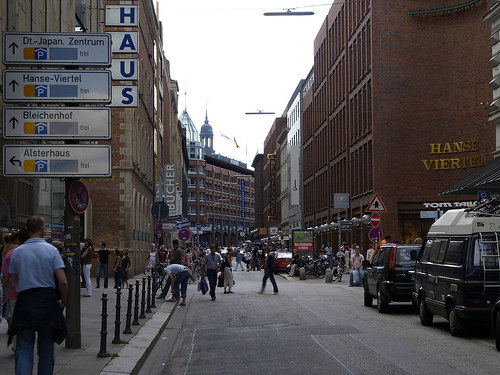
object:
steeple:
[204, 104, 209, 124]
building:
[0, 0, 500, 288]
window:
[444, 240, 464, 263]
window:
[428, 239, 447, 263]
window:
[473, 239, 498, 267]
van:
[412, 208, 500, 331]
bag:
[349, 270, 363, 287]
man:
[347, 245, 364, 287]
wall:
[371, 0, 495, 246]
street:
[0, 235, 500, 375]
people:
[223, 248, 235, 295]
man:
[7, 214, 70, 375]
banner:
[166, 165, 177, 211]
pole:
[96, 292, 109, 357]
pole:
[110, 285, 121, 343]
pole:
[122, 283, 134, 335]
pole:
[145, 275, 152, 314]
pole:
[150, 272, 156, 308]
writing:
[422, 139, 486, 170]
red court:
[88, 273, 152, 355]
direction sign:
[3, 32, 112, 67]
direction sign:
[2, 69, 113, 104]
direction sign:
[3, 106, 110, 140]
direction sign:
[3, 144, 112, 179]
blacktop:
[164, 259, 500, 375]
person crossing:
[253, 246, 279, 296]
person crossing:
[221, 247, 235, 294]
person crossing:
[249, 245, 261, 271]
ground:
[356, 120, 379, 140]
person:
[200, 244, 222, 301]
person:
[156, 239, 183, 301]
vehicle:
[361, 243, 422, 314]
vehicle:
[270, 251, 292, 275]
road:
[0, 254, 497, 375]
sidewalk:
[0, 273, 180, 375]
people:
[80, 238, 94, 298]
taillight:
[388, 247, 397, 270]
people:
[255, 247, 279, 295]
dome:
[199, 123, 215, 159]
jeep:
[362, 243, 423, 313]